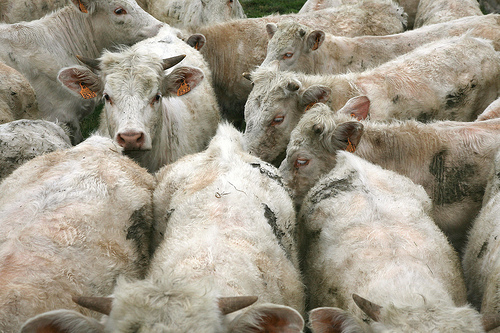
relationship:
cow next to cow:
[54, 23, 223, 174] [240, 28, 500, 168]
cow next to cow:
[240, 28, 500, 168] [279, 94, 498, 248]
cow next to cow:
[240, 28, 500, 168] [251, 13, 498, 78]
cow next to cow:
[251, 13, 498, 78] [177, 1, 413, 128]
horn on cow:
[71, 50, 102, 73] [54, 23, 223, 174]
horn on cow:
[158, 54, 184, 79] [54, 23, 223, 174]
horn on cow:
[313, 123, 325, 136] [279, 94, 498, 248]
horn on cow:
[286, 80, 300, 94] [240, 28, 500, 168]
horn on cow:
[240, 70, 252, 82] [240, 28, 500, 168]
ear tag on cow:
[77, 82, 98, 101] [54, 23, 223, 174]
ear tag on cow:
[174, 80, 192, 99] [54, 23, 223, 174]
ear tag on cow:
[343, 137, 357, 154] [279, 94, 498, 248]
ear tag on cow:
[303, 102, 316, 113] [240, 28, 500, 168]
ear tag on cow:
[313, 37, 320, 52] [251, 13, 498, 78]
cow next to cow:
[54, 23, 223, 174] [177, 1, 413, 128]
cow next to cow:
[177, 1, 413, 128] [251, 13, 498, 78]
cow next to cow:
[251, 13, 498, 78] [240, 28, 500, 168]